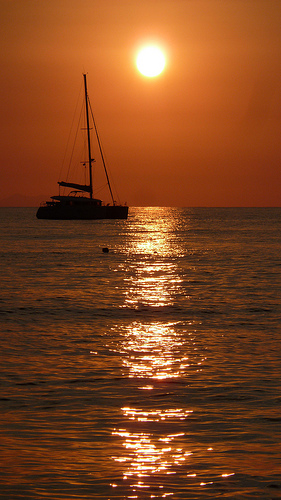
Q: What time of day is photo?
A: Evening.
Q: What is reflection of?
A: Sun.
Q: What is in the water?
A: A boat.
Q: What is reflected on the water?
A: The sun.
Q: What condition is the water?
A: Calm.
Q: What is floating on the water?
A: A boat.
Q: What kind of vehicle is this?
A: A boat.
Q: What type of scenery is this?
A: Seascape.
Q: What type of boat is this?
A: A sailboat.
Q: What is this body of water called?
A: The ocean.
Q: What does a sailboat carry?
A: Passengers.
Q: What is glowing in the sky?
A: The sun.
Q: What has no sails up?
A: The boat.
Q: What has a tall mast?
A: The boat.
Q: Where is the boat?
A: On the water.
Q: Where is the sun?
A: Above the boat.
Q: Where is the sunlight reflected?
A: On the water.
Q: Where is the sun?
A: In the sky.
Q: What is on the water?
A: The boat.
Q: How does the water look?
A: Calm.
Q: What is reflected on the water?
A: The sun.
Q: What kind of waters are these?
A: Calm waters.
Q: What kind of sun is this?
A: A bright sun.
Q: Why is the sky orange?
A: It's sunset.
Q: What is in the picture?
A: The ocean.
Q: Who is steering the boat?
A: The captain.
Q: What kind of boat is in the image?
A: A sailboat.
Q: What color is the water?
A: Shades of orange and white.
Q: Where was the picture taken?
A: On the water.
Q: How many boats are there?
A: One.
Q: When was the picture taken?
A: In the evening.